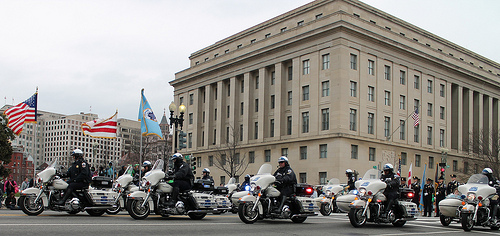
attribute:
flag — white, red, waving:
[0, 91, 38, 136]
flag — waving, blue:
[134, 96, 209, 159]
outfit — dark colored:
[266, 168, 295, 213]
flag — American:
[1, 93, 35, 136]